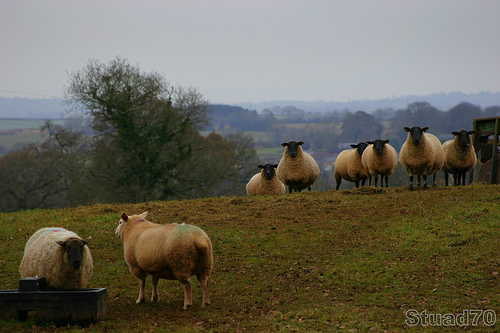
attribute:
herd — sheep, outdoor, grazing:
[246, 125, 479, 194]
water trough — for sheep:
[1, 274, 108, 322]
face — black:
[56, 234, 94, 270]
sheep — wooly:
[274, 140, 322, 193]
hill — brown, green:
[0, 184, 500, 331]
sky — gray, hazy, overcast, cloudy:
[0, 1, 500, 104]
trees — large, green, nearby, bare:
[1, 57, 261, 213]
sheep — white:
[113, 208, 216, 309]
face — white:
[115, 214, 126, 237]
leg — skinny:
[444, 171, 449, 187]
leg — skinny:
[452, 171, 460, 185]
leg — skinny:
[461, 172, 466, 186]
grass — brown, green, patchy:
[1, 182, 499, 332]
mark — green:
[176, 223, 195, 235]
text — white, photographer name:
[404, 307, 496, 327]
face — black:
[282, 140, 305, 158]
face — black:
[403, 126, 431, 143]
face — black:
[451, 129, 478, 149]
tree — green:
[66, 57, 210, 202]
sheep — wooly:
[245, 163, 286, 198]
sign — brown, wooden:
[466, 116, 499, 182]